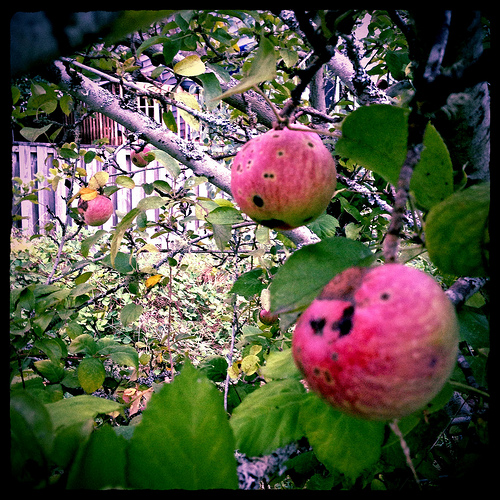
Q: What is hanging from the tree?
A: Fruit.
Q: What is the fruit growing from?
A: The tree.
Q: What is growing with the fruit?
A: Leaves.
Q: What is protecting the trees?
A: The fence.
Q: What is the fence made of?
A: Wood.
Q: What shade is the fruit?
A: Red.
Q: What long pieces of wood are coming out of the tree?
A: The branches.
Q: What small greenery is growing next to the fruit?
A: Leaves.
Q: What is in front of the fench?
A: A tree with fruit.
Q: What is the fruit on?
A: The tree.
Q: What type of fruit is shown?
A: Apple.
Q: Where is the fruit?
A: On the tree.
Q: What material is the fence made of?
A: Wood.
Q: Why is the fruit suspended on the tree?
A: It's growing.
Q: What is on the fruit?
A: Black dots.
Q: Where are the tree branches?
A: On top of the fence.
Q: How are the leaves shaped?
A: Wide and pointy.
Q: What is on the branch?
A: Leaves.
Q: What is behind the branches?
A: Fence.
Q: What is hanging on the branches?
A: Fruit.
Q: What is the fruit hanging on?
A: Branches.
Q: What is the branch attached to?
A: Tree.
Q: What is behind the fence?
A: Building.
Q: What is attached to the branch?
A: Fruit.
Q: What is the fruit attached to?
A: Branch.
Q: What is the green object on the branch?
A: Leaf.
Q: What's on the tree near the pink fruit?
A: Green leaf.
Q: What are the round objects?
A: Apples.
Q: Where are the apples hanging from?
A: A tree.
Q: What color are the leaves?
A: Green.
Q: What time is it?
A: Daytime.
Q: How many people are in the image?
A: None.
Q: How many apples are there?
A: Four.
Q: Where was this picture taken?
A: In an orchard.